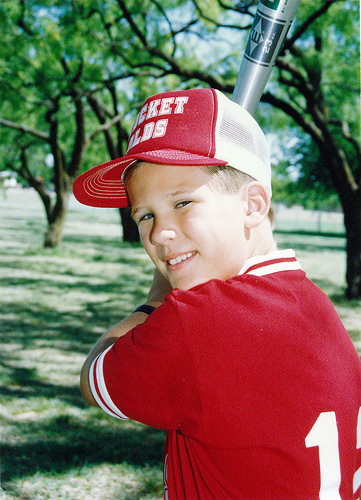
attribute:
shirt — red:
[87, 246, 360, 498]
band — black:
[136, 303, 153, 317]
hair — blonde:
[199, 159, 277, 228]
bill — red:
[72, 147, 226, 208]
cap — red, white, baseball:
[71, 88, 273, 210]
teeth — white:
[166, 248, 198, 265]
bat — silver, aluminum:
[229, 0, 303, 116]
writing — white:
[129, 102, 174, 145]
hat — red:
[70, 89, 282, 207]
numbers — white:
[308, 397, 358, 495]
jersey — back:
[83, 252, 352, 491]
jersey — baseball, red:
[77, 250, 336, 497]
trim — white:
[79, 340, 133, 427]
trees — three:
[7, 3, 357, 268]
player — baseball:
[87, 83, 331, 497]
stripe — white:
[77, 343, 131, 428]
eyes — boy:
[129, 196, 201, 220]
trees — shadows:
[14, 16, 244, 107]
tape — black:
[133, 303, 157, 314]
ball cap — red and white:
[69, 84, 273, 206]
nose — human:
[147, 221, 178, 250]